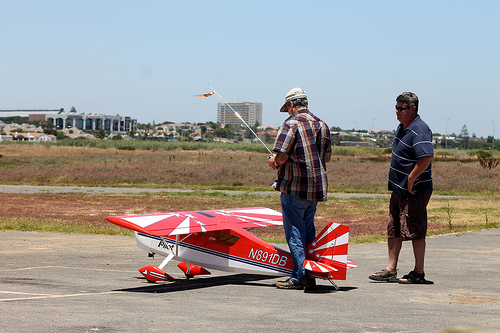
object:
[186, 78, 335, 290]
control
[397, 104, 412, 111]
sunglasses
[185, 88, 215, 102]
flag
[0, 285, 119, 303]
lines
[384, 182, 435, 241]
pants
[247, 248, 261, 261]
letters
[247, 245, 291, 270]
n891db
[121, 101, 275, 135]
distance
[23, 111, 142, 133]
building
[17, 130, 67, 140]
roof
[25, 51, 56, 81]
clouds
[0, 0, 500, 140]
sky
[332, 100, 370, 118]
clouds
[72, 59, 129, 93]
clouds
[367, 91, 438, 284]
man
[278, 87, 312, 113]
cap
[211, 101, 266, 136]
building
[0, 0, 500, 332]
background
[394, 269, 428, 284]
shoes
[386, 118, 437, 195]
shirt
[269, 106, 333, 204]
shirt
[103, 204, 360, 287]
airplane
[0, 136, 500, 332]
ground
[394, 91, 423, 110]
hair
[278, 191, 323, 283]
jeans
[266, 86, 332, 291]
man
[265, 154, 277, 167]
remote control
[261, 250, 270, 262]
numbers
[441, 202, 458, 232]
grass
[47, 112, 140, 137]
back